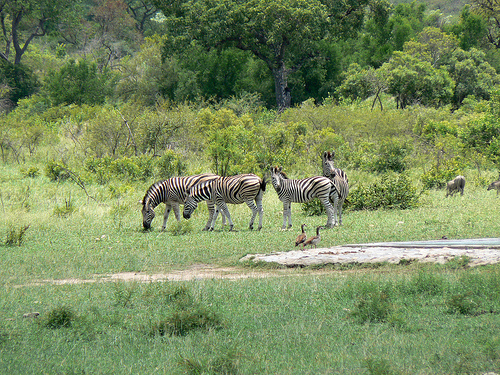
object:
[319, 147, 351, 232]
zebra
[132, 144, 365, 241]
group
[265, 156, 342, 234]
zebra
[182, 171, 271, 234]
zebra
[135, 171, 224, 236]
zebra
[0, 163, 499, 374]
grass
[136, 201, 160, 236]
head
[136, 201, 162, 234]
down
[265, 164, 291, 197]
head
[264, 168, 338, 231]
side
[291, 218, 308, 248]
bird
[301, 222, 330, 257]
bird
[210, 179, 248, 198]
stripes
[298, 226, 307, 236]
neck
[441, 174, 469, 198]
animal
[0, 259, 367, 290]
sand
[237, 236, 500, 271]
pavement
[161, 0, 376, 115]
tree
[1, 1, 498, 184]
brush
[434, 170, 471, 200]
zebra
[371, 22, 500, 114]
tree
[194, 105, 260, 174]
tree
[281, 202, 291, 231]
legs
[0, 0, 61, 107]
tree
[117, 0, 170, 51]
tree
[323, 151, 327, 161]
ear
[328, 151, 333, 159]
ear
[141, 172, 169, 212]
hair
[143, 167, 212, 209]
back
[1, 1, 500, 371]
picture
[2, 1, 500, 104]
woods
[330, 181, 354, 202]
tail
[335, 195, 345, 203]
hair